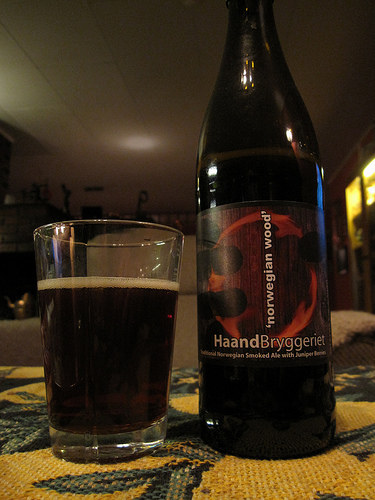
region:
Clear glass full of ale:
[31, 213, 184, 459]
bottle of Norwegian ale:
[200, 0, 337, 461]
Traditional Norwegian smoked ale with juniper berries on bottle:
[195, 347, 329, 362]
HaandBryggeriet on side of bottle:
[210, 329, 328, 352]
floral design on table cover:
[4, 366, 374, 499]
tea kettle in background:
[2, 292, 35, 316]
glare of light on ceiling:
[117, 124, 161, 158]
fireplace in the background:
[0, 129, 57, 324]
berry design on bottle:
[193, 233, 246, 320]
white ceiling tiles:
[8, 11, 155, 111]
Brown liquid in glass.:
[64, 298, 159, 372]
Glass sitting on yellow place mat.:
[61, 412, 129, 484]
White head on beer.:
[56, 267, 146, 291]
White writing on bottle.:
[218, 331, 302, 346]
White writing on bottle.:
[259, 257, 278, 327]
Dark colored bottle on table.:
[243, 392, 294, 446]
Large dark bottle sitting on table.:
[207, 59, 316, 317]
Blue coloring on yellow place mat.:
[92, 461, 195, 496]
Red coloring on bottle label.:
[207, 220, 307, 335]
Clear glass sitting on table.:
[38, 232, 186, 457]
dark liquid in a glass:
[30, 216, 196, 465]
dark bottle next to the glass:
[29, 2, 337, 463]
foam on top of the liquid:
[35, 273, 180, 294]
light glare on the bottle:
[202, 416, 222, 428]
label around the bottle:
[188, 194, 335, 368]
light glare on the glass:
[52, 224, 73, 237]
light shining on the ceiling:
[112, 133, 167, 158]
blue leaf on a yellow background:
[30, 456, 150, 496]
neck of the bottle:
[213, 1, 300, 74]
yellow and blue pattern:
[1, 365, 373, 497]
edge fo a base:
[97, 427, 136, 467]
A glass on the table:
[32, 221, 181, 458]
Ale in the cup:
[36, 279, 177, 435]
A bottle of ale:
[196, 0, 333, 460]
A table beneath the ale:
[0, 366, 373, 498]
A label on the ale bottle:
[195, 200, 331, 364]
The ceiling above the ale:
[0, 0, 372, 218]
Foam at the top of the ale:
[35, 277, 179, 289]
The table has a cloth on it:
[1, 366, 373, 499]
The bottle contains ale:
[196, 0, 337, 458]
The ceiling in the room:
[0, 1, 373, 216]